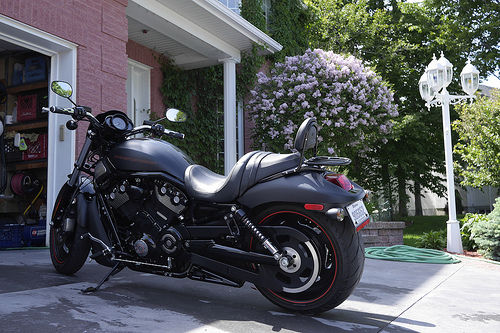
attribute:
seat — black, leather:
[194, 146, 298, 203]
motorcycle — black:
[39, 80, 371, 313]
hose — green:
[357, 235, 470, 279]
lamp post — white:
[435, 100, 472, 257]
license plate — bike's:
[329, 199, 396, 229]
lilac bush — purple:
[248, 46, 403, 172]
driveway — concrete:
[0, 242, 500, 331]